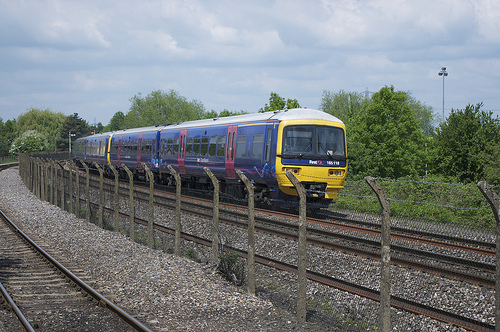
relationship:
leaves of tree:
[438, 140, 450, 150] [342, 100, 440, 204]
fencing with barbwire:
[7, 142, 498, 332] [375, 174, 479, 217]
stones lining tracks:
[153, 270, 201, 293] [5, 210, 147, 332]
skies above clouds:
[5, 52, 498, 156] [35, 106, 106, 136]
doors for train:
[222, 121, 240, 179] [67, 104, 349, 216]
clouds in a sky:
[37, 18, 116, 57] [4, 1, 491, 125]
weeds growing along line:
[214, 226, 248, 285] [14, 145, 484, 329]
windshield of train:
[278, 121, 348, 169] [67, 104, 349, 216]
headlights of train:
[278, 165, 346, 175] [67, 104, 349, 216]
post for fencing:
[267, 162, 321, 319] [19, 152, 500, 332]